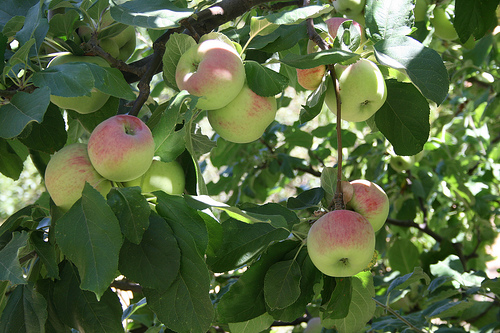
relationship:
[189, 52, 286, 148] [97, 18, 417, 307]
apples on tree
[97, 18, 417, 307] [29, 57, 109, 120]
tree with leaves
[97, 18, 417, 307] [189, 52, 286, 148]
tree with apples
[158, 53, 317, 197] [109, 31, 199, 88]
fruits on branch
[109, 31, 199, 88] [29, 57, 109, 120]
branch with leaves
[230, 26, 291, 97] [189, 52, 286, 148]
blossom on apples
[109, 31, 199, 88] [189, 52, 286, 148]
branch on apples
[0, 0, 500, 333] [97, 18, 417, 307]
tree on tree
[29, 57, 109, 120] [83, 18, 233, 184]
leaves on branches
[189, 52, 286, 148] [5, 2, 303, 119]
apples on branch